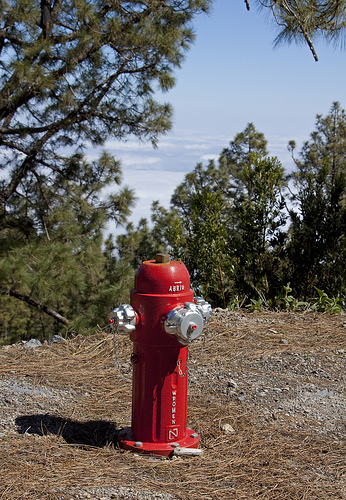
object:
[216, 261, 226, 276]
leaves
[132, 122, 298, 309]
tree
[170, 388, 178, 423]
white words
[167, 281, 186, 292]
white words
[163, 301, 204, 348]
knob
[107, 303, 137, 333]
knob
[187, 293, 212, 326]
knob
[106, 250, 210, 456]
fire hydrant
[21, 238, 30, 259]
green leaves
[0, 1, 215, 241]
tree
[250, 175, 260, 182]
leaves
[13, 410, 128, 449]
shadow